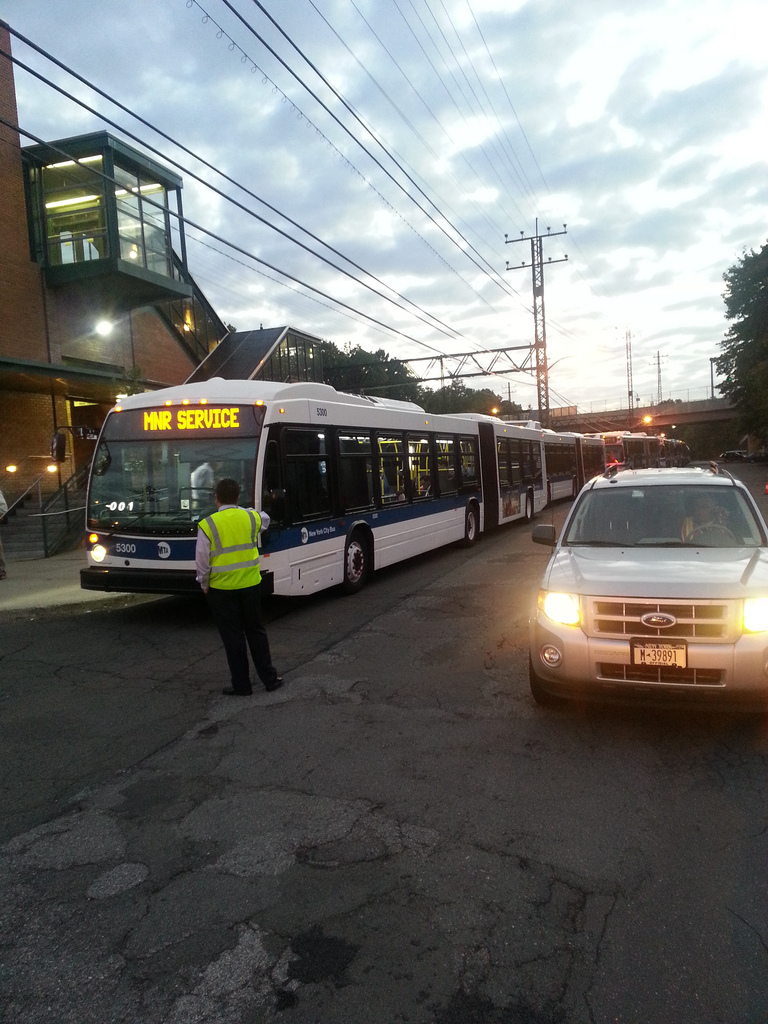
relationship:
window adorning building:
[114, 159, 172, 279] [2, 20, 207, 557]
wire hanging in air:
[0, 16, 474, 348] [2, 2, 744, 413]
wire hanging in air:
[1, 20, 489, 350] [2, 2, 744, 413]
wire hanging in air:
[186, 2, 569, 323] [2, 2, 744, 413]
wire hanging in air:
[252, 1, 595, 348] [2, 2, 744, 413]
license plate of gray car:
[627, 639, 687, 669] [521, 460, 744, 719]